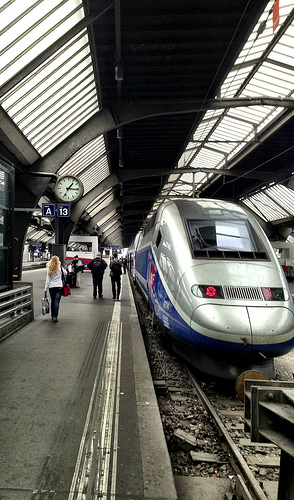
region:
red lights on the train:
[181, 274, 276, 304]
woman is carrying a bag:
[39, 285, 53, 312]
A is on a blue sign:
[35, 200, 56, 220]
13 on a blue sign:
[59, 204, 71, 216]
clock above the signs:
[56, 170, 86, 203]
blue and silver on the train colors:
[127, 210, 176, 309]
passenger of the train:
[107, 248, 125, 298]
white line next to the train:
[64, 311, 125, 499]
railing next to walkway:
[5, 280, 39, 343]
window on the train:
[180, 210, 274, 269]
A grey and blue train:
[130, 198, 292, 381]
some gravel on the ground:
[130, 281, 279, 480]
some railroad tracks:
[165, 346, 280, 498]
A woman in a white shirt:
[43, 254, 69, 324]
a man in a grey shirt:
[108, 251, 124, 301]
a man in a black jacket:
[85, 252, 106, 298]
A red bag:
[59, 267, 72, 297]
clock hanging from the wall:
[53, 174, 83, 203]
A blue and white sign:
[42, 203, 55, 216]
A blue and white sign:
[57, 201, 69, 216]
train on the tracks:
[126, 178, 292, 351]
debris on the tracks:
[167, 416, 225, 465]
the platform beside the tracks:
[19, 326, 143, 496]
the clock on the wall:
[48, 171, 86, 201]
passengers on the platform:
[43, 246, 125, 312]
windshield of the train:
[184, 218, 268, 257]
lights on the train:
[196, 282, 282, 303]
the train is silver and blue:
[141, 183, 293, 373]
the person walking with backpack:
[107, 247, 133, 306]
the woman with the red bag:
[32, 251, 75, 327]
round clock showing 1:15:
[54, 174, 85, 202]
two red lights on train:
[205, 283, 277, 299]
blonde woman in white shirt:
[40, 256, 71, 326]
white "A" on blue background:
[41, 204, 54, 217]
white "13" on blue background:
[56, 204, 69, 217]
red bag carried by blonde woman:
[63, 281, 72, 298]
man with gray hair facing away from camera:
[85, 250, 108, 299]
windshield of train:
[184, 216, 270, 262]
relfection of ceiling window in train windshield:
[214, 221, 253, 252]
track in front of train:
[174, 367, 268, 499]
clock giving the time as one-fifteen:
[51, 172, 85, 204]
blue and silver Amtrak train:
[123, 196, 292, 387]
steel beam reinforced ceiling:
[1, 0, 292, 282]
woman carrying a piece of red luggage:
[40, 253, 73, 323]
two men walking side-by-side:
[86, 251, 124, 302]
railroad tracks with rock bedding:
[140, 327, 279, 498]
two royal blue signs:
[40, 201, 72, 217]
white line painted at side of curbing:
[111, 263, 124, 320]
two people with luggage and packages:
[64, 253, 86, 289]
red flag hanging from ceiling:
[271, 1, 280, 34]